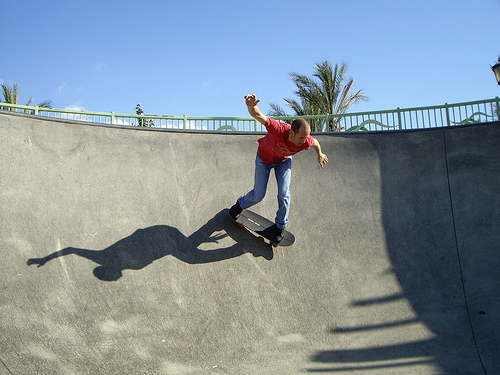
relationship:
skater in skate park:
[259, 118, 295, 226] [34, 68, 231, 371]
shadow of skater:
[83, 213, 199, 289] [259, 118, 295, 226]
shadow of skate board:
[230, 224, 252, 242] [250, 211, 261, 232]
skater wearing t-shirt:
[259, 118, 295, 226] [271, 125, 287, 151]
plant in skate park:
[305, 68, 359, 110] [34, 68, 231, 371]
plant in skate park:
[4, 91, 17, 100] [34, 68, 231, 371]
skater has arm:
[259, 118, 295, 226] [251, 106, 270, 123]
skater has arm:
[259, 118, 295, 226] [315, 143, 328, 157]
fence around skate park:
[372, 109, 486, 124] [34, 68, 231, 371]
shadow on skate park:
[392, 161, 496, 286] [34, 68, 231, 371]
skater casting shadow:
[259, 118, 295, 226] [83, 213, 199, 289]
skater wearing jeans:
[259, 118, 295, 226] [259, 164, 265, 191]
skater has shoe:
[259, 118, 295, 226] [233, 209, 239, 219]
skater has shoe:
[259, 118, 295, 226] [273, 228, 281, 240]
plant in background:
[305, 68, 359, 110] [23, 66, 238, 103]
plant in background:
[4, 91, 17, 100] [23, 66, 238, 103]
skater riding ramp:
[259, 118, 295, 226] [169, 151, 218, 364]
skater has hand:
[259, 118, 295, 226] [248, 94, 256, 107]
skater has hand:
[259, 118, 295, 226] [319, 154, 327, 165]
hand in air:
[248, 94, 256, 107] [257, 46, 300, 66]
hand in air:
[319, 154, 327, 165] [257, 46, 300, 66]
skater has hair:
[259, 118, 295, 226] [295, 121, 303, 129]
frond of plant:
[311, 61, 344, 127] [305, 68, 359, 110]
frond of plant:
[305, 100, 315, 108] [305, 68, 359, 110]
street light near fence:
[491, 65, 499, 79] [372, 109, 486, 124]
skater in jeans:
[259, 118, 295, 226] [259, 164, 265, 191]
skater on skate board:
[259, 118, 295, 226] [250, 211, 261, 232]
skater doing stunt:
[259, 118, 295, 226] [247, 112, 347, 249]